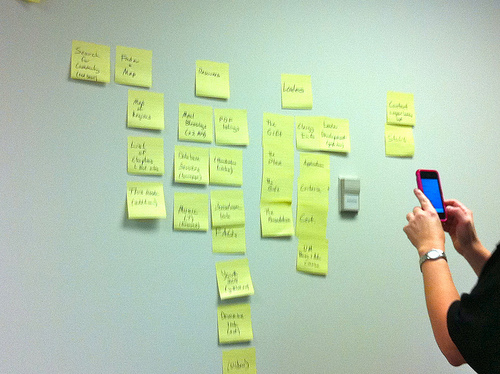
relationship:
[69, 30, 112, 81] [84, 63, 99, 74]
sticker has writing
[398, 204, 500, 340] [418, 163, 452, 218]
man holding cellphone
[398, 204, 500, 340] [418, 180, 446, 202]
man taking picture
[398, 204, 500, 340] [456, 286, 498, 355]
man wearing shirt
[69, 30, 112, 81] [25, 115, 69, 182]
sticker on wall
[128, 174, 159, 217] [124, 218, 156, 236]
paper has shadow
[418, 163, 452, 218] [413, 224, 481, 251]
cellphone in hands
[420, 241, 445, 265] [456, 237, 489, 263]
watch on wrist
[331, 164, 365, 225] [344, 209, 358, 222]
box has shadow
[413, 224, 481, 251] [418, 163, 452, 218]
hands holding cellphone